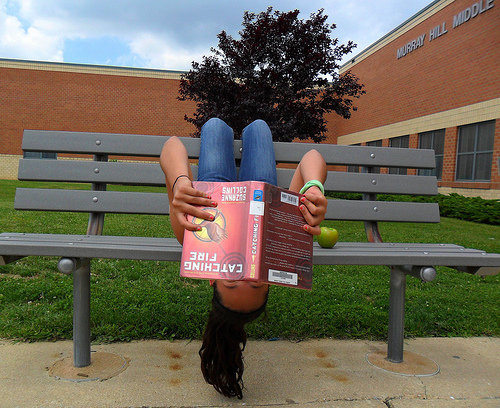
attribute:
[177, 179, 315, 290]
book — red, catching fire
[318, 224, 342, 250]
apple — green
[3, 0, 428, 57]
sky — blue